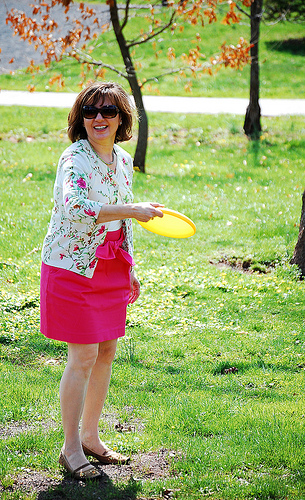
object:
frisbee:
[134, 197, 197, 244]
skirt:
[41, 256, 136, 349]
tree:
[0, 0, 249, 175]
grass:
[0, 107, 305, 500]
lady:
[33, 74, 171, 484]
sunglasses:
[79, 105, 120, 120]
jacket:
[41, 138, 136, 280]